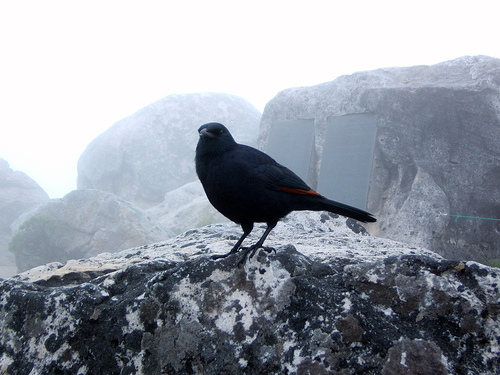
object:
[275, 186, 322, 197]
feather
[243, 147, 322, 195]
wing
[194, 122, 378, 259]
bird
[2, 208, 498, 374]
rock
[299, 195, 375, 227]
tail feathers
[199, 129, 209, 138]
beak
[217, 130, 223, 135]
eye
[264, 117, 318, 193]
plaque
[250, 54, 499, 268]
mountain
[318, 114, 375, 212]
plaque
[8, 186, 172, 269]
boulder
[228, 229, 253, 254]
leg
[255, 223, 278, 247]
leg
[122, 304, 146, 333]
white patch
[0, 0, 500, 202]
sky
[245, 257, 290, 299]
white patch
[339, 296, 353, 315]
white patch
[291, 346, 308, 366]
white patch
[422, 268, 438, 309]
white patch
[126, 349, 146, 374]
white patch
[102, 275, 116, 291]
white patch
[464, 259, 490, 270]
white patch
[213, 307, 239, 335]
white patch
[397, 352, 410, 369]
white patch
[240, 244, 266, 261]
foot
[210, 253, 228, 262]
foot